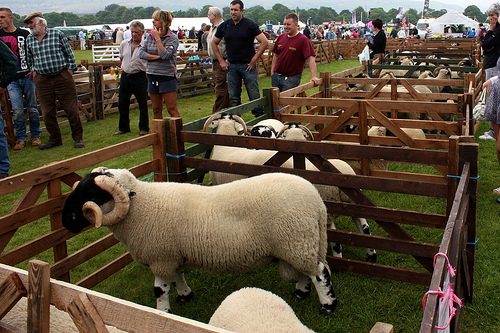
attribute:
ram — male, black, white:
[61, 167, 337, 315]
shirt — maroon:
[273, 31, 316, 75]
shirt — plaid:
[24, 28, 77, 74]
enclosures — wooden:
[0, 38, 486, 332]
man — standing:
[23, 12, 83, 150]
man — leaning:
[270, 13, 322, 90]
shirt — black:
[214, 16, 262, 63]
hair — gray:
[34, 16, 48, 29]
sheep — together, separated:
[0, 42, 473, 329]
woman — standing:
[140, 9, 181, 118]